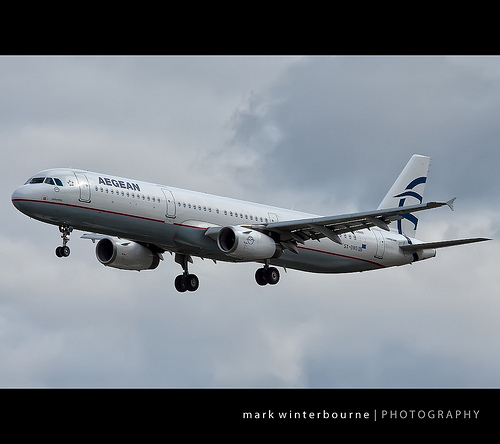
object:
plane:
[9, 153, 492, 291]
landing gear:
[172, 254, 203, 294]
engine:
[93, 235, 163, 271]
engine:
[211, 225, 285, 263]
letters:
[95, 174, 105, 189]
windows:
[156, 195, 162, 206]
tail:
[373, 153, 431, 236]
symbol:
[390, 172, 427, 233]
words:
[377, 406, 482, 425]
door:
[72, 169, 90, 204]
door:
[157, 186, 177, 220]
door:
[370, 226, 387, 262]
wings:
[256, 197, 456, 244]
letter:
[252, 410, 262, 420]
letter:
[320, 407, 329, 421]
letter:
[305, 409, 315, 421]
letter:
[424, 407, 435, 422]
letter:
[389, 409, 399, 421]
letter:
[286, 408, 293, 422]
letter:
[241, 409, 251, 421]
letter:
[264, 407, 276, 420]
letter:
[259, 411, 267, 419]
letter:
[131, 181, 142, 195]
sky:
[0, 56, 498, 389]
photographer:
[237, 406, 370, 425]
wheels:
[59, 245, 71, 257]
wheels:
[263, 266, 281, 286]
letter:
[111, 177, 120, 189]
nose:
[8, 185, 32, 206]